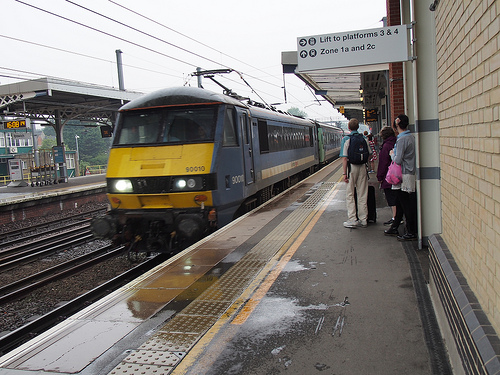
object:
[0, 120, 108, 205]
station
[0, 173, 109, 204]
street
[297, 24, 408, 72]
direction sign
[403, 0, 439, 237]
post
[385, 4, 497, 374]
wall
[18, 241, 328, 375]
puddle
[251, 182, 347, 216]
puddle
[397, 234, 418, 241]
shoe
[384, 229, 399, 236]
shoe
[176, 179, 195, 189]
head light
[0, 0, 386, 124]
clouds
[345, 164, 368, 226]
pants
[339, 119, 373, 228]
man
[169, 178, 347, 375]
yellow line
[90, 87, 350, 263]
car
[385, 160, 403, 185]
bag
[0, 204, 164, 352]
rail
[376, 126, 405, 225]
lady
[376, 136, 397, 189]
purple shirt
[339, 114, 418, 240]
people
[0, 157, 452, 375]
platform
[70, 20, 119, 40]
line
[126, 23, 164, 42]
line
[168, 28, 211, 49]
line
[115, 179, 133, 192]
head light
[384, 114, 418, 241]
person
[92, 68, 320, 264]
train engine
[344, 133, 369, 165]
backpack